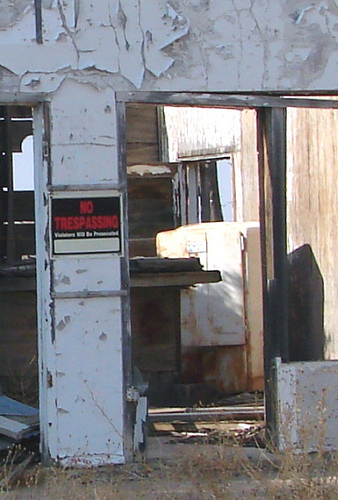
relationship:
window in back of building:
[9, 132, 38, 191] [0, 1, 335, 466]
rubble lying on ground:
[145, 395, 268, 447] [0, 397, 335, 499]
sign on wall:
[48, 187, 121, 257] [49, 92, 124, 468]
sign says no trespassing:
[48, 187, 121, 257] [54, 202, 120, 231]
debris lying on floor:
[145, 395, 268, 447] [0, 397, 335, 499]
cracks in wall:
[53, 0, 183, 70] [1, 2, 336, 94]